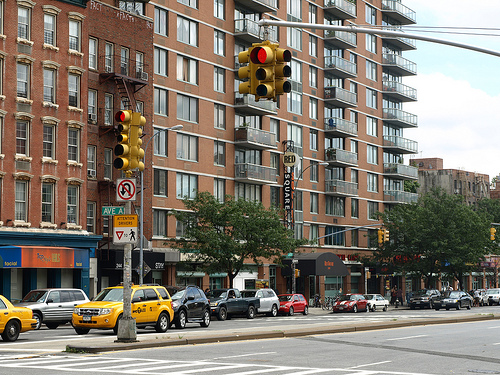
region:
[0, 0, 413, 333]
a large red multistory building very close to the street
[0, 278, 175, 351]
two taxis on the street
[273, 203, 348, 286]
black awning outside building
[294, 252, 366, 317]
red car with white stripes parked close to awning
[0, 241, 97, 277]
red and blue weathered looking awning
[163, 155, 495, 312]
trees in front of building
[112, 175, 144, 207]
no U-turn sign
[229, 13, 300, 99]
multi-sided yellow traffic light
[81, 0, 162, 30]
graffiti on building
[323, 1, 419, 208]
several balconies on building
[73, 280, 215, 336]
Cars moving in traffic.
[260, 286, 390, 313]
Cars parked on side of street.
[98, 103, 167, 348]
Traffic light on median strip in middle of street.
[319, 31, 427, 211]
Balconies outside rooms on brown building.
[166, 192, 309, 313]
Green tree growing on sidewalk in front of brown building.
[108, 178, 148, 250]
Traffic signs mounted on bottom of traffic light.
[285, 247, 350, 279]
Black awning over front of business.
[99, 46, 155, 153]
Balcony leading to fire escape on side of building.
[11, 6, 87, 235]
Windows along front of building.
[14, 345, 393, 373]
White crosswalk painted on street.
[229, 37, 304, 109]
a traffic light hanging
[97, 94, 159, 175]
a traffic light on a pole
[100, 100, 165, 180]
the traffic light is red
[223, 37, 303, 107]
the traffic light is red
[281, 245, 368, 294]
the awning of a building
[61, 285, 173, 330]
a taxi cab in the street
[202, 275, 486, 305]
cars parked beside the street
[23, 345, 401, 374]
the crosswalk is empty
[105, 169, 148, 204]
a no u turn sign on a pole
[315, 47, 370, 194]
balcony on a building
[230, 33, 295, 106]
A stoplight that is red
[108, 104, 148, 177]
A stoplight with one lit light and four dim ones.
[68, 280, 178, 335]
A yellow taxi SUV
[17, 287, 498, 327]
A long line of cars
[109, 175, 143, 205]
A sign indicating no U-turns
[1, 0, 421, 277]
A high-rise building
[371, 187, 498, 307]
A tree on the sidewalk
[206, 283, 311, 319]
Three cars of different colors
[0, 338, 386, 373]
White stripes on the ground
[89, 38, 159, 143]
A building's fire escape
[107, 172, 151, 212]
No U turns are permitted here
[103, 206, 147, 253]
Traffic must yield to pedestrians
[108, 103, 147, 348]
The red light is mounted on a pole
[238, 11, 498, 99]
The red light hangs from a pole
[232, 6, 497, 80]
The light pole is silver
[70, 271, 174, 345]
Yellow taxi waiting for the light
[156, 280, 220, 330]
Black car is following too close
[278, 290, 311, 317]
The red car is parked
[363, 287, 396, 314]
The white car is parked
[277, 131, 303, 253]
This is Red Square